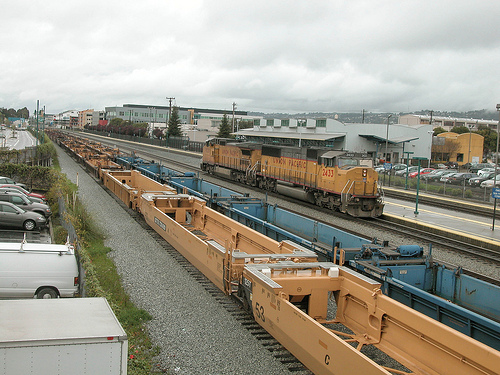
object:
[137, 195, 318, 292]
container car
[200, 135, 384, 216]
locomotive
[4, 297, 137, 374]
trailer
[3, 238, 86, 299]
van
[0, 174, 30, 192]
cars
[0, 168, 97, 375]
row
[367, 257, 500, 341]
train car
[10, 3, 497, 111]
sky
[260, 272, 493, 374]
train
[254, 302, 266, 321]
53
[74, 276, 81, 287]
tail light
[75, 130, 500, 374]
tracks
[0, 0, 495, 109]
clouds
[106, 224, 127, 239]
gravel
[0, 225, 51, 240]
parking  spot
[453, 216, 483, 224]
line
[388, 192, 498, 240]
asphalt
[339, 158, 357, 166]
window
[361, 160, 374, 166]
window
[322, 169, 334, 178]
number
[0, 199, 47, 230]
automobiles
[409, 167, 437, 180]
cars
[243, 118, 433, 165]
building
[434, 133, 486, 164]
business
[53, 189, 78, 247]
fence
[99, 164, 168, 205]
train car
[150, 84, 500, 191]
right side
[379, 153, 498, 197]
lot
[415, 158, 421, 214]
post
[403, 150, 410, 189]
post